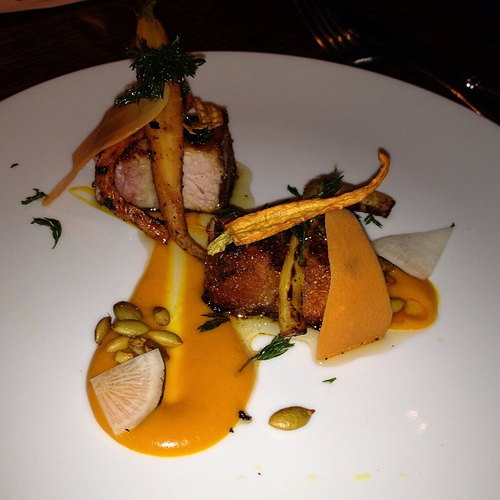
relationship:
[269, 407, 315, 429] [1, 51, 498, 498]
pumpkin seed on dish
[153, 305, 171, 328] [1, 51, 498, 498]
pumpkin seed on dish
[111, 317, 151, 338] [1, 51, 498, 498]
pumpkin seed on dish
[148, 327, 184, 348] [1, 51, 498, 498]
seed on dish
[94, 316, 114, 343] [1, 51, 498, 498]
pumpkin seed on dish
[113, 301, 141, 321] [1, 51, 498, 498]
pumpkin seed on dish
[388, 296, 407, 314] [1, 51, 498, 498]
seed on dish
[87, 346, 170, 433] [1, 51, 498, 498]
fruit on dish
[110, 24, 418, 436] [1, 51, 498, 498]
food on a dish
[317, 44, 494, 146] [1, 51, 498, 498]
fork laying next to dish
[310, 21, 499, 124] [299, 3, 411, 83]
fork on fork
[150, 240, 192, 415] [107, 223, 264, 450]
line in sauce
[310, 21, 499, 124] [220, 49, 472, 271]
fork lay next to plate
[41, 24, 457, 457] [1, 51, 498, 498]
food on dish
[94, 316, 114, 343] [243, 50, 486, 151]
pumpkin seed on plate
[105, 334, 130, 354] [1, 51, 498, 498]
seed on dish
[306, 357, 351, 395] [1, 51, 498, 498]
green on dish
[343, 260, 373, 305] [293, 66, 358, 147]
yellow on plate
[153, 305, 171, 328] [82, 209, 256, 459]
pumpkin seed in sauce